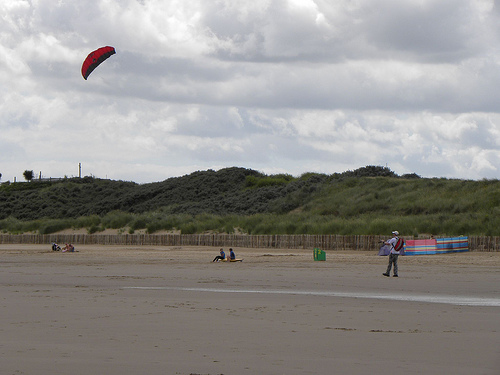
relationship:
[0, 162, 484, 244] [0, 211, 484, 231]
hill with greenery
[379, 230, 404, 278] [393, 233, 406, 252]
man with a backpack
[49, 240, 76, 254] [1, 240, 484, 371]
people on a beach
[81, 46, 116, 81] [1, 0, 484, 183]
kite in a sky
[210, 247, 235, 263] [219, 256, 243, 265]
people on a blanket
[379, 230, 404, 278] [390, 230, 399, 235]
man wearing a hat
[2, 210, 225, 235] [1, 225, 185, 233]
grass growing in sand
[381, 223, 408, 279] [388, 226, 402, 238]
man has head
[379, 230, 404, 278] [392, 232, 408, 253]
man wears backpack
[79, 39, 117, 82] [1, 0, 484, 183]
kite in sky